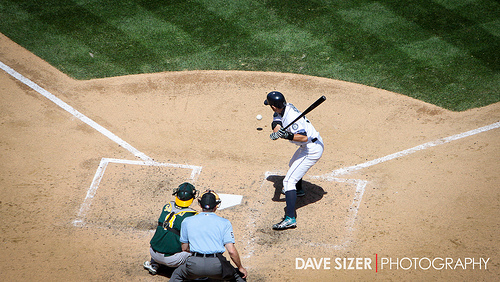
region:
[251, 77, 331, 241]
a man swinging his bat at a ball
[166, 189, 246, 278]
an umpire crouching behind a player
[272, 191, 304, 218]
blue socks on a leg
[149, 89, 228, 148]
sand on a baseball field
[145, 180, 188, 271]
a catcher squatting behind home plate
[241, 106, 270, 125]
a white baseball flying through the air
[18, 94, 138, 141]
white lines draw in the sand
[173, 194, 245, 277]
a man wearing a blue shirt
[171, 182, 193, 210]
a baseball player wearing a yellow hat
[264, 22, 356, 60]
cut grass on a baseball field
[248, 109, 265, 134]
The baseball and its shadow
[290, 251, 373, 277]
The name of the photographer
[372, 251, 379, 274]
The red line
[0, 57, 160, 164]
The third base line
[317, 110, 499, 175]
The first base line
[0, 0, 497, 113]
The infield grass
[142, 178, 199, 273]
The catcher in the green and yellow uniform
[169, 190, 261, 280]
The umpire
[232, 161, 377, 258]
The batter's box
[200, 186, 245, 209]
The base called home plate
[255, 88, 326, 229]
the batter is ready to swing at a baseball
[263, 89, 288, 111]
the batter has a black helmet on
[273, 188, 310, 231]
the batter is wearing blue baseball shoes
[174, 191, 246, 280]
the umpire is wearing protective gear on his head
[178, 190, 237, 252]
the umpire is wearing a blue shirt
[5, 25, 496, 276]
a red clay home plate and green grass field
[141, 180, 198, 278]
the catcher is wearing his cap backwards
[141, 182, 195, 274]
the catcher is squatting to catch baseball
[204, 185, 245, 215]
the home plate is white and trianguler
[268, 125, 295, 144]
the batter is wearing baseball gloves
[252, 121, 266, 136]
The baseball's shadow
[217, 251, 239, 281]
The ball pouch attached to the umpire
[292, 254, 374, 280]
The photographer who took the photo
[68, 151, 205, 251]
Batter's box for right handed hitters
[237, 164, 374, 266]
The currently used batter's box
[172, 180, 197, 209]
The yellow and green helmet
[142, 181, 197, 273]
The catcher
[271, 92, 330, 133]
The bat of the player on offense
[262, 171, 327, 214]
The batter's shadow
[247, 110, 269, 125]
A baseball after it has been pitched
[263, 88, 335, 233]
the batter is getting ready to swing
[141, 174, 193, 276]
The catcher is behind home plate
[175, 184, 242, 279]
the umpire is behind the catcher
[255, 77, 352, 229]
The baseball player is holding a bat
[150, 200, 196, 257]
the catcher is wearing a green shirt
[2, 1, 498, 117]
the grass on the field is very green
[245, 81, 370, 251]
the player is watching the ball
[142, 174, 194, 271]
the catcher is watching the ball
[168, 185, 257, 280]
the umpire is watching the ball